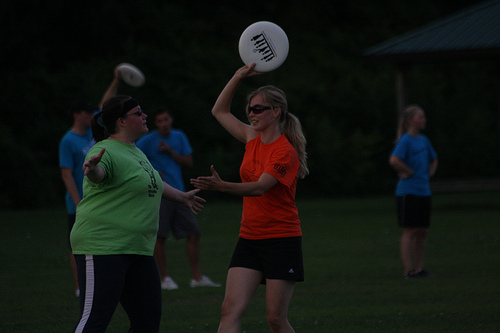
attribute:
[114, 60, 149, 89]
frisbee — white, round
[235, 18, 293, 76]
frisbee — white, round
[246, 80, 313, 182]
hair — long, blonde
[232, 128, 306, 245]
shirt — orange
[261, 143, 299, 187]
sleeve — short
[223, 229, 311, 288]
shorts — black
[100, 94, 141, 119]
headband — black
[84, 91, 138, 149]
hair — dark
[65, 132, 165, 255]
shirt — green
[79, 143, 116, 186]
sleeve — short